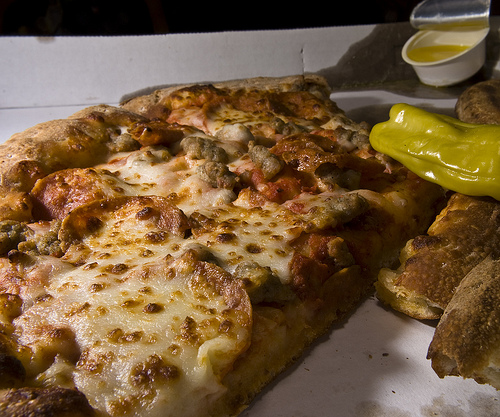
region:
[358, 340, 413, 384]
brown crumb on the paper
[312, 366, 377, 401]
white box on the surface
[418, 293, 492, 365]
crust on pizza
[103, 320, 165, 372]
white gooey cheese on pizza top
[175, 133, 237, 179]
sausage on the pizza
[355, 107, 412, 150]
tip of banana pepper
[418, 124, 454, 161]
shine on the pepper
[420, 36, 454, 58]
melted butter in cup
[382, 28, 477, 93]
white cup filled with butter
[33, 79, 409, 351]
large slice of pizza in box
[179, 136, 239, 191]
sausage on a pizza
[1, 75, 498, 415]
pizza and a pepper on cardboard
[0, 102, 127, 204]
the crust of pizza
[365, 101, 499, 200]
a green peppercini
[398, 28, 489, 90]
plastic cup with sauce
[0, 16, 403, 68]
a cardboard box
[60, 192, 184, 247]
pepperoni covered in cheese on pizza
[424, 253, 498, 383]
crust of a pizza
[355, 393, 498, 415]
grease stains on cardboard box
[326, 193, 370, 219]
sausage on pizza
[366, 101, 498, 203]
whole banana pepper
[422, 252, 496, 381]
crust of a piece of pizza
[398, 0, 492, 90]
cheesy garlic sauce in plastic cup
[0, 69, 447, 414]
3 pieces of sausage and pepperoni pizza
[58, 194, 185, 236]
piece of hidden pepperoni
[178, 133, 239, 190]
2 pieces of delicious looking sausage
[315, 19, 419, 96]
grease stain on the pizza box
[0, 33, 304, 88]
white cardboard that makes up the side of the pizza box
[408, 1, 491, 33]
tinfoil lid to the garlic cheese sauce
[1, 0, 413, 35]
black abyss where you can see nothing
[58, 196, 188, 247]
Pepperoni on top of pizza.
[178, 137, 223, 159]
Sausage on top of pizza.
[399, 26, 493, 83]
Pizza sauce on top of box.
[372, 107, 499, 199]
Green pepper on top of pizza.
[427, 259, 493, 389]
Pizza crust on top of table.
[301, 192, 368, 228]
Large piece of meat on pizza.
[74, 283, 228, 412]
Melted cheese on top of pizza.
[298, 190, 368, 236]
Large piece of sausage on pizza.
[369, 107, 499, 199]
Big piece of pepper on a box.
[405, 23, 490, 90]
Small cup of sauce on pizza.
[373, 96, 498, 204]
Yellow banana pepper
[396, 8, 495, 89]
Yellow dipping sauce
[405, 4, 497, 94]
Dipping sauce in container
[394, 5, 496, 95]
Shiny container with lid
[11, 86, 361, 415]
Pizza with cheese and meat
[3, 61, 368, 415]
Pizza with white cheese and red sauce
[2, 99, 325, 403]
Pizza containing brown crust covered with cheese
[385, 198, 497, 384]
Brown crusted pizza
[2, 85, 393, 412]
Red pizza with white cheese and meat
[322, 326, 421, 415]
White cardboard